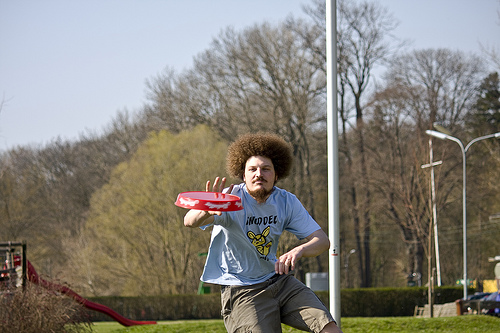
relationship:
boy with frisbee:
[196, 136, 381, 331] [172, 178, 257, 227]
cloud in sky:
[34, 10, 134, 65] [17, 22, 122, 132]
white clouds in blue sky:
[49, 62, 121, 94] [2, 1, 497, 153]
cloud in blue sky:
[0, 0, 499, 150] [2, 1, 499, 152]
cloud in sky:
[0, 0, 499, 150] [0, 2, 226, 133]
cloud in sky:
[0, 0, 499, 150] [27, 14, 262, 120]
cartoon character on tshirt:
[243, 222, 273, 258] [196, 182, 323, 284]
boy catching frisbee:
[182, 129, 349, 333] [173, 187, 243, 209]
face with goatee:
[243, 156, 277, 196] [251, 187, 269, 198]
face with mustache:
[243, 156, 277, 196] [250, 175, 268, 184]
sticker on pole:
[329, 247, 340, 259] [324, 0, 344, 332]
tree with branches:
[276, 9, 381, 289] [356, 37, 378, 93]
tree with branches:
[276, 9, 381, 289] [298, 24, 325, 70]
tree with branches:
[276, 9, 381, 289] [337, 0, 362, 61]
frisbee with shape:
[118, 172, 250, 246] [204, 200, 227, 210]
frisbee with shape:
[118, 172, 250, 246] [233, 199, 240, 207]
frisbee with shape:
[118, 172, 250, 246] [176, 194, 197, 209]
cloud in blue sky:
[0, 0, 499, 150] [41, 52, 108, 87]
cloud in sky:
[0, 0, 499, 150] [1, 0, 499, 152]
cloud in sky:
[0, 0, 499, 150] [1, 5, 493, 114]